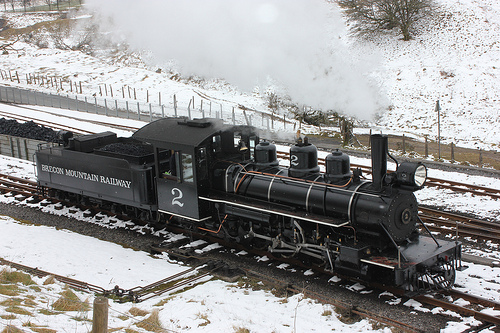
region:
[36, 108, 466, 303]
old timey locomotive in the photo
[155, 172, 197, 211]
the number "2" is on the side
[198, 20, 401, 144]
steam is coming out of the locomotive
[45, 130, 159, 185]
the train appears to be hauling coal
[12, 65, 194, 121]
fencing lines the side of the tracks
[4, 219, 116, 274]
snow is on the ground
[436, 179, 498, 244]
another set of tracks runs parallel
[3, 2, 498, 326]
the photo is very picturesque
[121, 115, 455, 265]
the engine is black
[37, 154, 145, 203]
the train is part of a mountain railway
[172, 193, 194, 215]
number 2 is written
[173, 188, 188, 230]
number 2 is written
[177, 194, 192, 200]
number 2 is written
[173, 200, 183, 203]
number 2 is written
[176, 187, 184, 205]
number 2 is written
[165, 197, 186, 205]
number 2 is written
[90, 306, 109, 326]
THE POST IS WOODEN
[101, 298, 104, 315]
THE POST IS WOODEN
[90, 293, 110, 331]
THE POST IS WOODEN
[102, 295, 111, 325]
THE POST IS WOODEN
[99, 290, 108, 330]
THE POST IS WOODEN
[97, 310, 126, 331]
THE POST IS WOODEN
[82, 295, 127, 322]
THE POST IS WOODEN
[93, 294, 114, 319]
THE POST IS WOODEN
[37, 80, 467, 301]
black train on a railroad track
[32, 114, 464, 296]
Black train on a snowy railroad track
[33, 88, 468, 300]
Black Mountain Railway train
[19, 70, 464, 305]
Black train with the number 2 on it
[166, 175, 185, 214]
a white number 2 on a train where the engineer is stationed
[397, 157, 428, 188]
lamp light on the front of the black train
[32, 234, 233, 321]
snow on the ground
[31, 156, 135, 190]
the name of the railway on the side of the train car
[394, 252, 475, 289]
bumper of the train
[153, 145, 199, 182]
engineers side right window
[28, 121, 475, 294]
a black train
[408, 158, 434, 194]
a headlight on a train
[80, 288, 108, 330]
a wooden fence post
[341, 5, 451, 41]
a tree on a hillside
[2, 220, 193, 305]
snow beside the tracks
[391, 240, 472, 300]
a cattle guard on the front of a train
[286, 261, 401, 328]
gravel along the tracks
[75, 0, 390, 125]
a steam cloud coming out of a train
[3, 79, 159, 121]
a road running parrallel with the train tracks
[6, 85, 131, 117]
a fence alongside a road